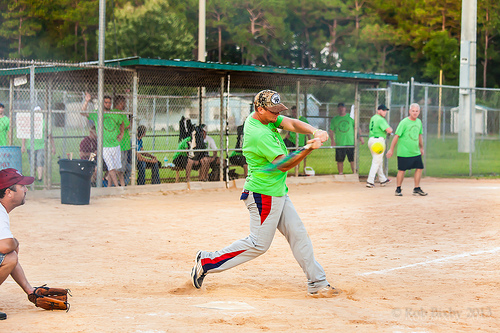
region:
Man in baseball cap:
[246, 85, 293, 118]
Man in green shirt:
[237, 111, 301, 201]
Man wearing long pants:
[182, 167, 338, 298]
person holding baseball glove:
[24, 275, 81, 321]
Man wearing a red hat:
[0, 163, 36, 216]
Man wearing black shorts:
[392, 144, 432, 180]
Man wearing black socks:
[387, 179, 430, 196]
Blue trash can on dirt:
[50, 149, 110, 210]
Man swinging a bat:
[224, 87, 330, 229]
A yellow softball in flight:
[364, 136, 392, 162]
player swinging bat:
[176, 89, 353, 307]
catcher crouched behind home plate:
[0, 163, 79, 328]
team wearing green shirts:
[82, 103, 437, 201]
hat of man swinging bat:
[249, 86, 285, 118]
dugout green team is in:
[57, 75, 401, 170]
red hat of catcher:
[3, 164, 33, 187]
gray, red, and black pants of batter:
[200, 195, 325, 275]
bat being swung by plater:
[279, 138, 327, 177]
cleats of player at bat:
[188, 255, 340, 303]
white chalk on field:
[344, 222, 499, 293]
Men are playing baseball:
[2, 93, 449, 313]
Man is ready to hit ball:
[239, 88, 345, 291]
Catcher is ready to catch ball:
[3, 165, 78, 321]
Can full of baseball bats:
[42, 133, 114, 223]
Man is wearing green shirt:
[232, 88, 314, 198]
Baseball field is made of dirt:
[71, 211, 457, 331]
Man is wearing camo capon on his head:
[251, 84, 290, 135]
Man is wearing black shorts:
[393, 144, 430, 184]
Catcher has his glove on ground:
[1, 161, 84, 318]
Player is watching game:
[85, 86, 132, 175]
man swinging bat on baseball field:
[209, 60, 373, 307]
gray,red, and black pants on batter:
[216, 193, 342, 289]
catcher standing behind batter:
[13, 180, 102, 325]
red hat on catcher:
[1, 149, 51, 201]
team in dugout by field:
[66, 83, 446, 180]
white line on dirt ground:
[350, 210, 492, 296]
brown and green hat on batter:
[245, 77, 323, 124]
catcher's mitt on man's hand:
[29, 283, 98, 320]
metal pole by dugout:
[82, 5, 115, 182]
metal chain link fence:
[51, 66, 497, 161]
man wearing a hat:
[206, 72, 349, 295]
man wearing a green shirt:
[170, 67, 346, 328]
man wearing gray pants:
[146, 85, 376, 302]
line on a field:
[376, 250, 481, 271]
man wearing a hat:
[0, 166, 71, 314]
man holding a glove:
[8, 161, 76, 326]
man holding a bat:
[171, 78, 338, 298]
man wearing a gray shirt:
[0, 162, 73, 323]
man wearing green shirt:
[380, 92, 425, 195]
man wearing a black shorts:
[390, 84, 430, 217]